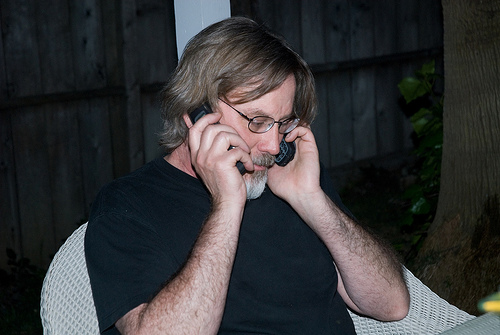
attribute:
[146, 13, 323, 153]
hair — brown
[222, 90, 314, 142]
glasses — black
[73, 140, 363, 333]
shirt — black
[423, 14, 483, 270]
trunk — brown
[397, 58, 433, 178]
leaves — green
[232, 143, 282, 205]
beard — white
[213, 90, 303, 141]
reading glasses — black framed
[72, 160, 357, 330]
t-shirt — black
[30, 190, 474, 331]
chair — white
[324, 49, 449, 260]
plants — green leaf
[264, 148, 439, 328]
arm — hairy , white 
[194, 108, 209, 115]
telephone — black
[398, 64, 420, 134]
leaves — green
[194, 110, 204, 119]
cell phone — black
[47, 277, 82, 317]
wicker chair — white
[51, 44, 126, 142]
fence — brown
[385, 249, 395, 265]
hair — brown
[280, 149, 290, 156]
buttons — black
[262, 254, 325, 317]
t-shirt — black, short sleeve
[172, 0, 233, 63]
post — white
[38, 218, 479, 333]
chair — white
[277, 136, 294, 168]
cellphone — black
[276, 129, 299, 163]
cellphone — black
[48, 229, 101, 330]
chair — white, wicker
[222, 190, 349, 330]
shirt — short sleeve, black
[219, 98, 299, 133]
glasses — black, wire rimmed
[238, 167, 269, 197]
beard — white, brown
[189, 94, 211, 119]
phone — black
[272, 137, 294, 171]
phone — black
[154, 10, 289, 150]
hair — brown, shaggy